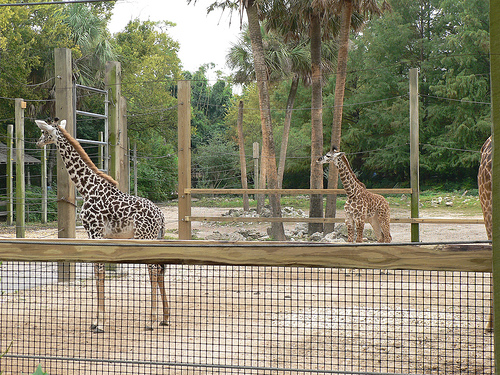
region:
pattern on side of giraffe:
[99, 196, 133, 221]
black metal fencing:
[230, 268, 420, 365]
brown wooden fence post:
[134, 247, 391, 267]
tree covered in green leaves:
[121, 22, 187, 77]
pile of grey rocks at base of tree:
[221, 194, 313, 229]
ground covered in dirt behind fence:
[220, 280, 400, 359]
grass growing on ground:
[423, 189, 477, 211]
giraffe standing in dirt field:
[30, 113, 200, 330]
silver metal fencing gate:
[72, 80, 117, 142]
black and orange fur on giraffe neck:
[58, 127, 124, 193]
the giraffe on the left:
[28, 110, 188, 337]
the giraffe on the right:
[292, 125, 414, 299]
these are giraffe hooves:
[90, 301, 185, 348]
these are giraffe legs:
[70, 251, 184, 336]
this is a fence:
[2, 233, 497, 373]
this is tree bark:
[261, 91, 271, 139]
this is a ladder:
[63, 83, 129, 293]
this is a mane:
[337, 143, 371, 199]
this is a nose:
[35, 138, 48, 148]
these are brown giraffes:
[19, 102, 420, 359]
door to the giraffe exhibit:
[23, 66, 167, 227]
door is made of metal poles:
[67, 68, 142, 251]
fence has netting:
[73, 272, 398, 368]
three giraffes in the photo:
[19, 115, 490, 203]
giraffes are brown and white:
[60, 127, 167, 252]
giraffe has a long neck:
[43, 134, 111, 198]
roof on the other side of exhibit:
[13, 141, 44, 180]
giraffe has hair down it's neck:
[51, 126, 130, 194]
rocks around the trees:
[209, 196, 339, 237]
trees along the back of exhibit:
[61, 26, 494, 174]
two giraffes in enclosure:
[44, 102, 413, 315]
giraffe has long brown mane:
[56, 118, 128, 193]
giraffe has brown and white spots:
[32, 125, 131, 219]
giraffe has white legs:
[62, 226, 187, 356]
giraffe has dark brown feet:
[86, 316, 172, 348]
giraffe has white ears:
[42, 100, 84, 150]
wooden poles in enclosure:
[110, 63, 297, 275]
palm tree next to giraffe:
[195, 1, 397, 246]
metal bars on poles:
[79, 70, 122, 159]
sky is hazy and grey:
[108, 2, 243, 71]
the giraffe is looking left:
[30, 118, 175, 328]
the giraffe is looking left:
[318, 146, 392, 254]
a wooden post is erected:
[173, 77, 195, 242]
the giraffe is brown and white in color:
[35, 117, 175, 329]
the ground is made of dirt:
[2, 210, 497, 372]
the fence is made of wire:
[6, 261, 497, 368]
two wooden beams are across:
[181, 185, 494, 224]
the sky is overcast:
[108, 1, 256, 99]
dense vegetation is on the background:
[0, 0, 494, 205]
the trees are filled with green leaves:
[1, 0, 498, 196]